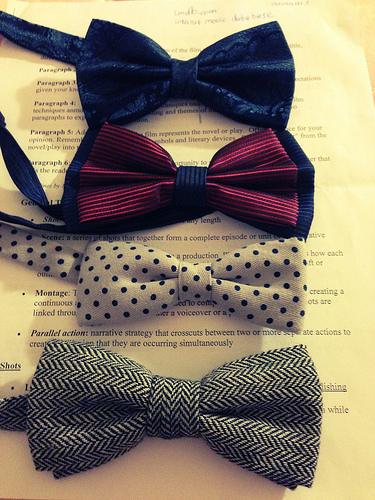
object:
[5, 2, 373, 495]
paper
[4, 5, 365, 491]
bowties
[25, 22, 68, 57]
fabric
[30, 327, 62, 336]
word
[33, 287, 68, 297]
word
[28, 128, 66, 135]
word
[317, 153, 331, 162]
word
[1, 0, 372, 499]
book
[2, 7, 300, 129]
bowtie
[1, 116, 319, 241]
bowtie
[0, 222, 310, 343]
bowtie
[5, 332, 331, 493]
bowtie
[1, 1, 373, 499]
page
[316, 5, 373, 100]
part